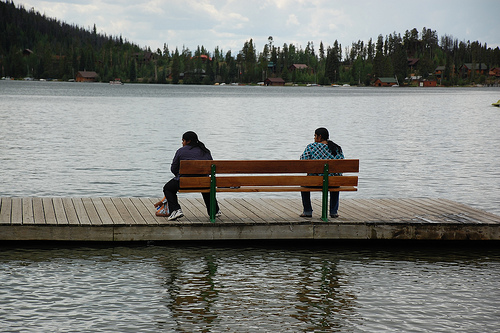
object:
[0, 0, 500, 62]
sky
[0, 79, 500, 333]
water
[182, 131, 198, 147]
head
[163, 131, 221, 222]
woman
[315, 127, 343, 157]
hair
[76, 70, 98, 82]
house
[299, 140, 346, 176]
shirt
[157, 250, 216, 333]
reflection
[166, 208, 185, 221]
shoe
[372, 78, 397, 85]
houses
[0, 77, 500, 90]
shore line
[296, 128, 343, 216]
people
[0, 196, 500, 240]
pier